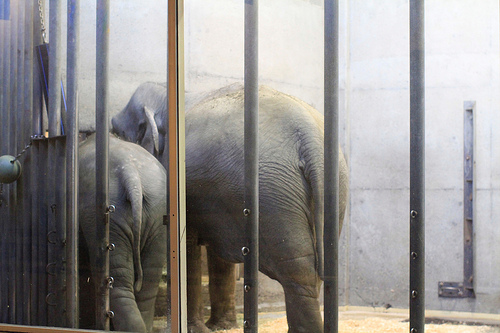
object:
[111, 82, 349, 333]
elephant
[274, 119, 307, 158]
gray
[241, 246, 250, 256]
rings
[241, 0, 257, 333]
metal pole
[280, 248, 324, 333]
leg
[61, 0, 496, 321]
wall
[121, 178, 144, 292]
tail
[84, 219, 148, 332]
legs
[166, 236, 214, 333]
legs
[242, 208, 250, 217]
ring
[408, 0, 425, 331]
pole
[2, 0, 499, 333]
fence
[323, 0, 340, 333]
pole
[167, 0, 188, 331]
pole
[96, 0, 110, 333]
pole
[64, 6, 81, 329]
pole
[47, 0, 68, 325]
pole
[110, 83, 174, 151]
head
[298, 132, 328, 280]
tail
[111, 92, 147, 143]
ear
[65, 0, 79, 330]
rod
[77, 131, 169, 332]
elephant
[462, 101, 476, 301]
bar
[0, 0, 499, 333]
cage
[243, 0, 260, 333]
bar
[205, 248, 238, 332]
leg